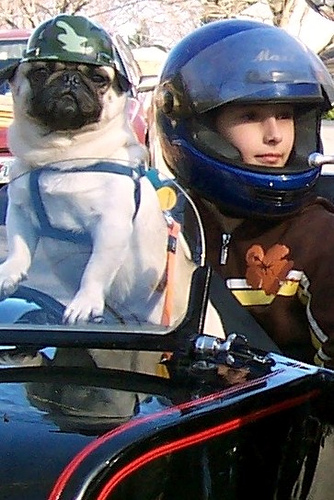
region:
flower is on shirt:
[240, 254, 297, 301]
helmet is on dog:
[0, 22, 120, 136]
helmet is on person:
[166, 24, 325, 213]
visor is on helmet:
[177, 24, 331, 106]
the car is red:
[2, 28, 155, 166]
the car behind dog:
[0, 25, 156, 184]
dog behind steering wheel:
[4, 73, 145, 338]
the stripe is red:
[63, 385, 279, 483]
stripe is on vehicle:
[84, 408, 270, 488]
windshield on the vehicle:
[13, 161, 233, 379]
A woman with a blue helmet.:
[152, 16, 333, 211]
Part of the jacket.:
[307, 229, 327, 256]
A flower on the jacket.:
[243, 245, 293, 295]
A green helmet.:
[21, 14, 118, 68]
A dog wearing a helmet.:
[1, 14, 132, 127]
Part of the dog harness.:
[30, 197, 51, 225]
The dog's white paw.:
[59, 288, 104, 326]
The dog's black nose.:
[62, 70, 79, 92]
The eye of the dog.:
[89, 73, 104, 82]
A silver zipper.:
[219, 232, 231, 264]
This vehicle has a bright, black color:
[61, 391, 87, 476]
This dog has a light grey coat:
[90, 221, 122, 309]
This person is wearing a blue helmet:
[229, 68, 255, 126]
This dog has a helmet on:
[36, 26, 79, 97]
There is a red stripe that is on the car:
[201, 430, 207, 446]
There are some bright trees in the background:
[140, 11, 156, 42]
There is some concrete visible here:
[322, 474, 325, 489]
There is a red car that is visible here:
[12, 27, 17, 59]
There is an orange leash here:
[167, 260, 181, 301]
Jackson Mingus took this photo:
[77, 356, 202, 497]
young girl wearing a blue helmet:
[147, 13, 332, 370]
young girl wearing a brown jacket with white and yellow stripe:
[145, 15, 332, 370]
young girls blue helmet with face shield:
[150, 18, 332, 217]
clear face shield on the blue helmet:
[177, 25, 333, 122]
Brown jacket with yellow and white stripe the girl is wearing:
[176, 189, 332, 373]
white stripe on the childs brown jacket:
[226, 272, 331, 363]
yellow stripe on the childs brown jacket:
[227, 280, 320, 366]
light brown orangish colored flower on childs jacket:
[241, 239, 293, 299]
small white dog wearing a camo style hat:
[0, 14, 170, 328]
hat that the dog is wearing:
[13, 13, 127, 77]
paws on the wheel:
[1, 273, 131, 345]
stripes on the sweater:
[216, 247, 330, 353]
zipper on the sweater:
[211, 227, 271, 284]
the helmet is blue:
[168, 41, 325, 208]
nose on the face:
[256, 114, 287, 149]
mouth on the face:
[249, 146, 301, 165]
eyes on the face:
[237, 106, 300, 128]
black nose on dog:
[51, 71, 90, 93]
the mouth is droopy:
[45, 93, 93, 115]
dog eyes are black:
[32, 70, 111, 88]